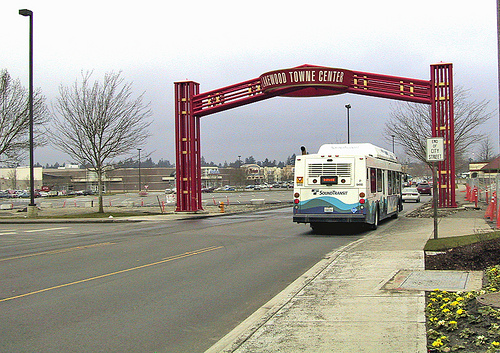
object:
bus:
[290, 141, 408, 233]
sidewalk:
[217, 184, 499, 352]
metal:
[171, 77, 202, 212]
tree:
[36, 67, 158, 213]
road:
[0, 193, 434, 353]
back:
[291, 154, 372, 219]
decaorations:
[180, 187, 190, 197]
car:
[399, 187, 419, 204]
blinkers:
[357, 191, 365, 199]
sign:
[423, 136, 445, 165]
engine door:
[303, 157, 356, 188]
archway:
[170, 61, 459, 215]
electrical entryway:
[396, 269, 470, 290]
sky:
[0, 0, 498, 170]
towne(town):
[286, 69, 317, 85]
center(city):
[315, 71, 345, 83]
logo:
[254, 67, 344, 90]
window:
[367, 165, 375, 193]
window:
[375, 166, 383, 194]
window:
[386, 170, 392, 198]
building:
[0, 164, 42, 192]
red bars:
[445, 63, 456, 209]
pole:
[430, 165, 438, 240]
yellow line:
[0, 243, 225, 302]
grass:
[421, 230, 499, 251]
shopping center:
[42, 164, 295, 192]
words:
[260, 72, 288, 88]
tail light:
[357, 198, 365, 206]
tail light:
[291, 191, 301, 199]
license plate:
[320, 205, 335, 214]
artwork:
[294, 188, 364, 216]